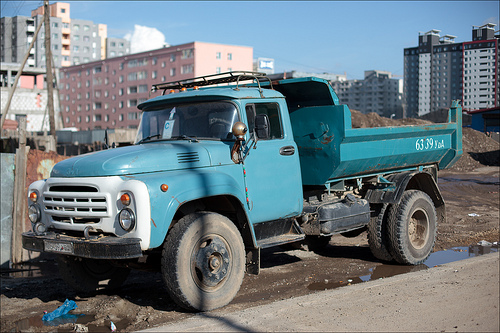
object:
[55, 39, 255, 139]
building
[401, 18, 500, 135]
building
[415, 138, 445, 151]
number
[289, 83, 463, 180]
bed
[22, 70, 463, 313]
blue truck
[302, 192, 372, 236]
gas tank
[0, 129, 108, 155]
fence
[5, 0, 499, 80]
sky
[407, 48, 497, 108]
wall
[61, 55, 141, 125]
wall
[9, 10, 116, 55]
wall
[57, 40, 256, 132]
house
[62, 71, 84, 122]
windows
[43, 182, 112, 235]
grill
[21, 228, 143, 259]
bumper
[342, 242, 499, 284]
puddle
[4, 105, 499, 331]
dirt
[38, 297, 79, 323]
bag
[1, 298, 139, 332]
puddle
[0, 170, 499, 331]
ground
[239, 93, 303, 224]
door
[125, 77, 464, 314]
side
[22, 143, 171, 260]
front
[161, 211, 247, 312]
tire